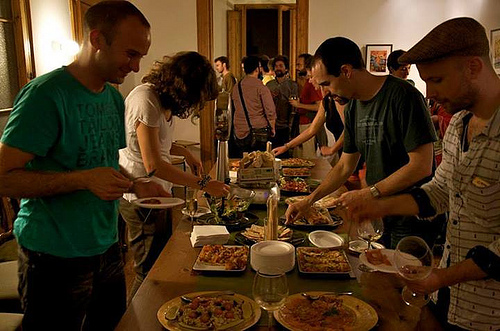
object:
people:
[1, 0, 166, 329]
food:
[155, 284, 261, 331]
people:
[350, 5, 498, 331]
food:
[291, 242, 354, 277]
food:
[363, 243, 398, 268]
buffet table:
[111, 128, 431, 330]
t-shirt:
[1, 69, 130, 259]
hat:
[389, 16, 492, 69]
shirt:
[109, 84, 187, 196]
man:
[296, 28, 438, 256]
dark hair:
[309, 33, 366, 81]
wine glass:
[387, 233, 440, 305]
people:
[218, 49, 282, 157]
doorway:
[187, 0, 313, 153]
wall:
[308, 3, 497, 72]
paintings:
[364, 41, 394, 78]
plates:
[248, 236, 296, 259]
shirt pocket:
[458, 165, 497, 221]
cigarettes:
[465, 174, 494, 193]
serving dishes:
[192, 240, 251, 274]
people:
[211, 53, 241, 116]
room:
[0, 2, 500, 331]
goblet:
[248, 261, 295, 330]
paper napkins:
[190, 221, 229, 239]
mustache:
[273, 67, 287, 78]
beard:
[332, 93, 352, 106]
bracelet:
[194, 173, 214, 190]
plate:
[131, 193, 187, 212]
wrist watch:
[366, 182, 383, 201]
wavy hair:
[136, 47, 225, 125]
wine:
[396, 261, 429, 280]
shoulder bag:
[237, 78, 276, 152]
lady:
[107, 36, 227, 298]